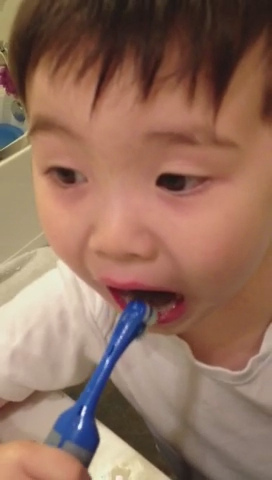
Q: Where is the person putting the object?
A: In the mouth.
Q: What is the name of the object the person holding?
A: Toothbrush.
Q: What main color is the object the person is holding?
A: Blue.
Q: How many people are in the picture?
A: One.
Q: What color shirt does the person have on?
A: White.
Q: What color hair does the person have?
A: Black.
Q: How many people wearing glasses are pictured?
A: None.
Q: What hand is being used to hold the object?
A: Right.